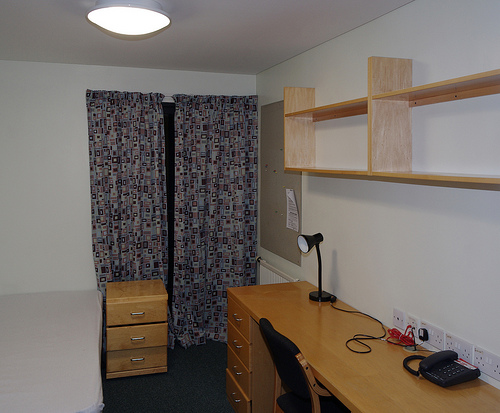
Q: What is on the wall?
A: Shelves.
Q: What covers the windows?
A: Curtains.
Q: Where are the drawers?
A: Desk.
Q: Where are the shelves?
A: On wall.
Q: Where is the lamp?
A: On desk.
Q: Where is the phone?
A: On desk.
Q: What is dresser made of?
A: Wood.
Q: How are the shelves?
A: Empty.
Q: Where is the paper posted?
A: On bulletin.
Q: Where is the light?
A: Ceiling.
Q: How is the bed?
A: Unmade.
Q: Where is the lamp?
A: On the desk.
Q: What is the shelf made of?
A: Wood.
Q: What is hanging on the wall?
A: Curtains.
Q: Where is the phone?
A: On the desk.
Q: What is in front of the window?
A: A three-drawer nightstand.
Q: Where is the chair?
A: Pushed into the desk.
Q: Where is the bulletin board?
A: To the left of the desk.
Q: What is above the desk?
A: Wooden shelving.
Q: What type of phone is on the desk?
A: Landline.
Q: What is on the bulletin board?
A: A piece of paper.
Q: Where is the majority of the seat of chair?
A: Underneath desk.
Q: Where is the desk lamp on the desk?
A: On left hand end of desk.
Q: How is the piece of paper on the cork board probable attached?
A: With thumb tacks or push pins.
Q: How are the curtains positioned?
A: They are closed.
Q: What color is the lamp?
A: Black.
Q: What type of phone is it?
A: Corded.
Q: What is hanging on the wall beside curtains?
A: Corkboard.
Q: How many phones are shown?
A: 1.